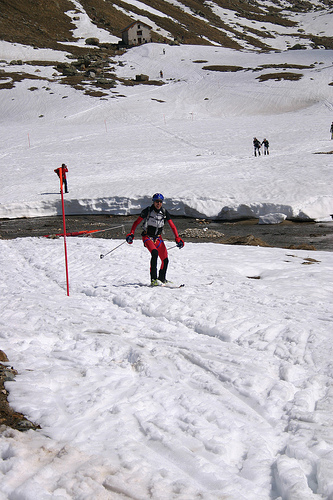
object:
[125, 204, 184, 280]
clothing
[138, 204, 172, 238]
top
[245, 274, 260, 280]
spot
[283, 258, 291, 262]
spot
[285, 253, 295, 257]
spot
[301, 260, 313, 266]
spot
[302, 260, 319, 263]
spot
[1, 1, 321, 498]
snow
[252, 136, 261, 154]
person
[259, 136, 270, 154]
person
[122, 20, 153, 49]
building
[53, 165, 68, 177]
red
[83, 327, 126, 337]
ski track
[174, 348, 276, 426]
ski track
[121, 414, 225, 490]
ski track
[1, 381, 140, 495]
ski track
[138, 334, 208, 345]
ski track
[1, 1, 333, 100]
hill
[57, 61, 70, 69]
boulder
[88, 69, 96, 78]
boulder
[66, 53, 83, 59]
boulder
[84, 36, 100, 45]
boulder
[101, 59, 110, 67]
boulder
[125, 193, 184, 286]
man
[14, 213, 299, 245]
stream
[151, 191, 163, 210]
skier's head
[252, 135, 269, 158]
two people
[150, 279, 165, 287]
person's feet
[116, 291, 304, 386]
patterns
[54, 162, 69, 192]
guy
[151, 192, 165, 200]
blue helmet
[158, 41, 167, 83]
skiers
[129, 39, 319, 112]
snow drifts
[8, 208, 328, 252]
river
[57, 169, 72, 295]
pole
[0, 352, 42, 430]
rocks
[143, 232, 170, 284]
pants